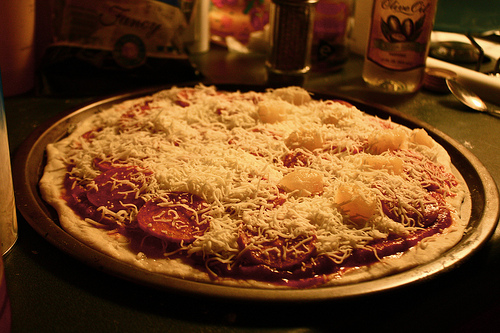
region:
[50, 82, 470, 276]
the pizza in pan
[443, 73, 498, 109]
spoon on the table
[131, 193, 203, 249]
pepperoni on the pizza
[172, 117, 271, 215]
cheese on the pizza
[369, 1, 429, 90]
olive oil on table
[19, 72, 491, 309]
the pan is round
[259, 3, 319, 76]
pepper on the table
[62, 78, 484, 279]
the pizza is uncooked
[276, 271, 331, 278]
sauce on the pizza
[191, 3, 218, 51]
salt on the table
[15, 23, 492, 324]
an unfinished pizza on a tray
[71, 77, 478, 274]
this pizza has pepperoni, cheese and some kind of vegetable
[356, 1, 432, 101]
a bottle in the background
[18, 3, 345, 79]
items on the table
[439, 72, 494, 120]
a spoon in the background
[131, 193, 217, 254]
a pepperoni on the pizza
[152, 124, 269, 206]
this is mozzarella cheese on the pizza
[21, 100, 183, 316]
the pizza pan is metal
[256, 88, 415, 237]
the vegetables are white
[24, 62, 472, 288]
this pizza is about to be cooked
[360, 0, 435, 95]
a bottle on the table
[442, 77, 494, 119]
a spoon on the table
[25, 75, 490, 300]
a silver platter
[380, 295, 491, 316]
the table under the platter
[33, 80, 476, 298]
a pizza in a platter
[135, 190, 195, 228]
a pepperoni on the pizza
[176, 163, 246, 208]
cheese on the pizza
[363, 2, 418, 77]
a bottle of olive oil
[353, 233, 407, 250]
sauce on the pizza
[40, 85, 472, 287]
Frozen pizza on the pan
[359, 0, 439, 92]
Bottle of olive oil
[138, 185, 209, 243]
Frozen piece of pepperoni on the pizza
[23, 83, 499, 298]
Pan used to hold the frozen pizza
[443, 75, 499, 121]
Silver spoon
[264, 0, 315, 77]
Small container of spice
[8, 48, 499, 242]
Small counter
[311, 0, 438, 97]
Couple of bottles next to the frozen pizza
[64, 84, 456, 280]
Cheese on the frozen pizza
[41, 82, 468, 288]
pizza on metal plate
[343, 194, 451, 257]
tomato sauce on pizza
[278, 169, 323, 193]
pineapple piece on pizza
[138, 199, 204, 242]
slice of pepperoni on pizza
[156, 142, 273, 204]
shredded cheese on pizza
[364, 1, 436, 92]
bottle of beer on table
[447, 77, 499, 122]
silver metal spoon on table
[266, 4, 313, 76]
pepper shaker on table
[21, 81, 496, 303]
grey metal pizza pan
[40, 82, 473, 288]
uncooked pizza on pan